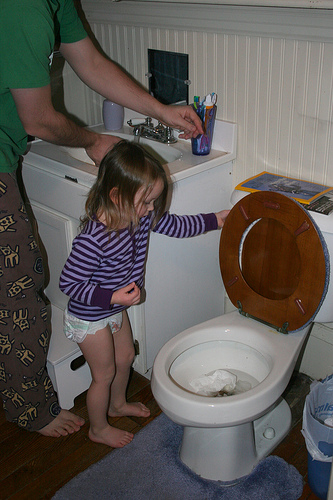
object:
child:
[58, 138, 231, 450]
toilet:
[149, 173, 333, 481]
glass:
[189, 104, 217, 156]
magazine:
[233, 171, 332, 204]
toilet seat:
[217, 190, 330, 333]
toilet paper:
[186, 368, 238, 394]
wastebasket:
[302, 378, 332, 496]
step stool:
[47, 305, 92, 410]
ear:
[109, 186, 122, 208]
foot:
[86, 425, 134, 450]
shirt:
[59, 213, 219, 322]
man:
[0, 3, 205, 439]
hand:
[160, 103, 206, 140]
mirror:
[145, 48, 189, 106]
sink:
[65, 130, 186, 167]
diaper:
[62, 307, 122, 344]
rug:
[52, 413, 303, 499]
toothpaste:
[197, 94, 213, 151]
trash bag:
[301, 375, 333, 461]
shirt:
[0, 0, 90, 175]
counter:
[26, 118, 229, 183]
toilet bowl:
[165, 327, 277, 399]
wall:
[253, 4, 331, 141]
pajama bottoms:
[0, 172, 64, 434]